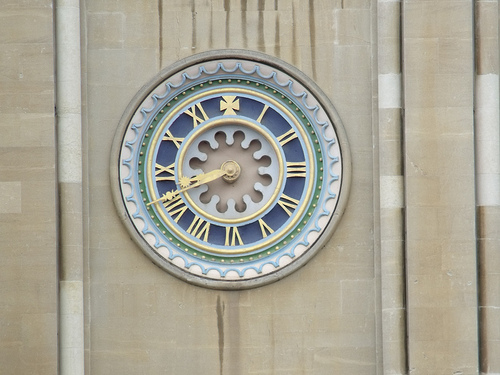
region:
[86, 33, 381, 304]
an analog clock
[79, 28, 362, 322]
the clock has roman numerals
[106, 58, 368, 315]
the numbers on the clock are gold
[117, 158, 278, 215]
the minute and hour hands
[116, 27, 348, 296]
the hands of the clock are gold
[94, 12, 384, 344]
the clock looks old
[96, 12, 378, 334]
the clock is wrapped in a pattern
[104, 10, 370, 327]
the clock is on the side of a building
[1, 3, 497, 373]
the side of a stone building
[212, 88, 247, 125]
a cross on a clock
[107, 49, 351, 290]
ornate clock on a brick wall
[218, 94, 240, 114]
iron cross used as the number 12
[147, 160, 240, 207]
decorative hands of a clock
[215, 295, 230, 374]
water stain on the brick wall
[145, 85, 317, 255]
gold, dark blue, and light blue clock face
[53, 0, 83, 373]
vertical light grey bricks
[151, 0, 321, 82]
9 water stains on top of the clock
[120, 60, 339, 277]
light blue scalloped decoration around clock face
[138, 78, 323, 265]
green ring with gold dots around the clock face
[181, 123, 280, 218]
raised light blue scalloped inner clock face decoration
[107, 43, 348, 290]
the time is 8:41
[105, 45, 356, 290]
the clock has roman numerals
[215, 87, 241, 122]
the XII is replaced by a symbol similar to the plus sign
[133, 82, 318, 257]
the numerals and hands are gold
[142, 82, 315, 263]
the numeral area background is blue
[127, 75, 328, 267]
the minutes markers are a small golden dot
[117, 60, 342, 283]
the light blue outer decoration resembles a gear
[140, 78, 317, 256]
the numerals are surrounded by light blue and gold circles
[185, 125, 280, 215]
the inner design resembles a gear or sprocket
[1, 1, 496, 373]
the wall has the appearance of being built from stone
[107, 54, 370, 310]
a clock on a wall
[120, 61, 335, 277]
a blue and white clock on the wall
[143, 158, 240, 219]
gold hands on clock on the wall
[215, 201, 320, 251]
roman numbers on clock on the wall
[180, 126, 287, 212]
wave design on the clock on the wall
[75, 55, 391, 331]
concrete out around the clock on the wall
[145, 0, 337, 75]
wavy design above the clock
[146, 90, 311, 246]
blue under the numbers on the clock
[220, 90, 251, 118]
a fancy x at the top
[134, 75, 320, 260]
a green circle with dots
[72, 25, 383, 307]
Clock on side of building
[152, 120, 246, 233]
Hands of the clock are gold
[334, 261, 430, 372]
Side of building is scratched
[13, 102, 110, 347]
The building is made of concrete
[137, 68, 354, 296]
The clock is designed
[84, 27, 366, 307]
the clock is a circle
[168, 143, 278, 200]
Center of clock is an odd shape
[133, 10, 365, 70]
Water stains above the clock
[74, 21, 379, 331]
The clock includes many colors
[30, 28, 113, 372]
Concrete blocks stacked on each other